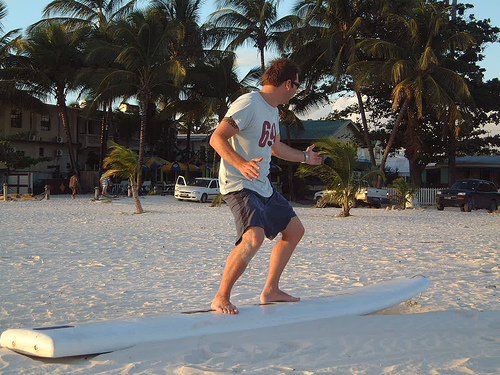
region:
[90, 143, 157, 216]
small palm tree on the beach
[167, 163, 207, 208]
car door is open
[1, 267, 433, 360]
surfboard is on the sand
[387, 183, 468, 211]
fence next to the car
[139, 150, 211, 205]
orange and blue umbrellas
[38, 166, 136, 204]
people on the beach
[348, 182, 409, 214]
brake lights on the truck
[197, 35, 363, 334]
man standing on the surfboard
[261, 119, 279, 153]
69 is written in red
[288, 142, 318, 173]
man is wearing a watch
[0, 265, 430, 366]
a long white surfboard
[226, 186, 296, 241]
a man's blue shorts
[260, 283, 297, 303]
a man's barefoot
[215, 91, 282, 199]
a man's shirt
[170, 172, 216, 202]
part of a white car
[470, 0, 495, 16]
part of a blue sky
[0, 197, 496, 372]
a large section of beach sand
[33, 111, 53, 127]
a window of a building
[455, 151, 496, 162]
the roof of a building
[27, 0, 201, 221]
a large green tree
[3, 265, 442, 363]
white surfboard on sand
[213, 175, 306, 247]
blue shorts with black stripe on side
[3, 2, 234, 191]
green palm trees bordering sand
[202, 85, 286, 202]
grey t-shirt with red numbers on front of shirt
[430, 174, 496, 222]
black car parked in sand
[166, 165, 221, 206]
white car with open car door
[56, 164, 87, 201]
person walking on sand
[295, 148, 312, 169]
metal watch on wrist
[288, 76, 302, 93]
black shades on person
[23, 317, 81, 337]
black rectangular design on surface of white surfboard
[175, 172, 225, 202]
car parked on beach front with doors open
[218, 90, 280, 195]
man wearing a tee shirt with number "69"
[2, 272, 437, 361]
man practicing riding surf board in the sand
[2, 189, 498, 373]
white clean sand on beach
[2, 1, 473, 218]
bushy palm trees grow wildly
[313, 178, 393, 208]
truck with tail lights engaged parked on sand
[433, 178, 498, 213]
black suv is parked facing sun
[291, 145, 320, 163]
wearing a watch on left hand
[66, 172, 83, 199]
person walking under shaded trees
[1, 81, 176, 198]
very large house of hotel faces beach front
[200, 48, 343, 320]
Man on a surfboard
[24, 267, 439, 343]
Surfboard out of water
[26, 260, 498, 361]
Surfboard in the sand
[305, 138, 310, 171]
Watch on the man's wrist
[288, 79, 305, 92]
Sunglasses on the man's face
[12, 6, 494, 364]
Photo taken during the day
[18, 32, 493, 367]
Photo taken at a beach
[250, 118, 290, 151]
69 written on the tee shirt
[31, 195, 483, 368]
The sand is white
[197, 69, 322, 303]
Man wearing shorts and a tee shirt